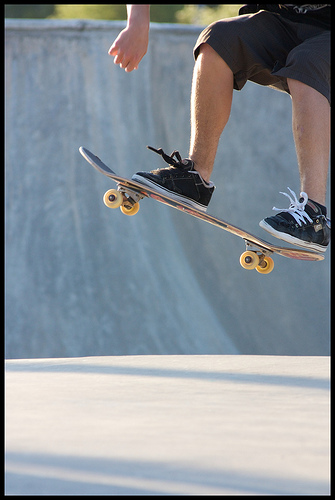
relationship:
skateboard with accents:
[73, 135, 325, 285] [146, 190, 235, 233]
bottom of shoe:
[258, 219, 327, 253] [259, 187, 330, 249]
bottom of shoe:
[130, 172, 207, 212] [132, 146, 215, 211]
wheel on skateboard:
[120, 196, 139, 216] [78, 142, 325, 275]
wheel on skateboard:
[102, 188, 124, 209] [78, 142, 325, 275]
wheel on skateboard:
[239, 250, 259, 270] [78, 142, 325, 275]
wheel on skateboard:
[255, 256, 274, 274] [78, 142, 325, 275]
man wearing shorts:
[108, 0, 335, 255] [194, 0, 332, 105]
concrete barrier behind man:
[24, 49, 333, 319] [108, 0, 335, 255]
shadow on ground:
[4, 354, 330, 391] [2, 353, 333, 496]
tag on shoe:
[313, 223, 324, 235] [256, 193, 331, 255]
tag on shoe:
[300, 196, 319, 214] [256, 193, 331, 255]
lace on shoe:
[145, 144, 191, 181] [131, 145, 217, 214]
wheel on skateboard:
[118, 189, 142, 217] [78, 142, 325, 275]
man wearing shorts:
[106, 1, 331, 252] [188, 7, 334, 100]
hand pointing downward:
[107, 3, 149, 71] [109, 49, 144, 78]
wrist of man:
[121, 9, 159, 44] [108, 0, 335, 255]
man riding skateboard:
[108, 0, 335, 255] [52, 148, 299, 325]